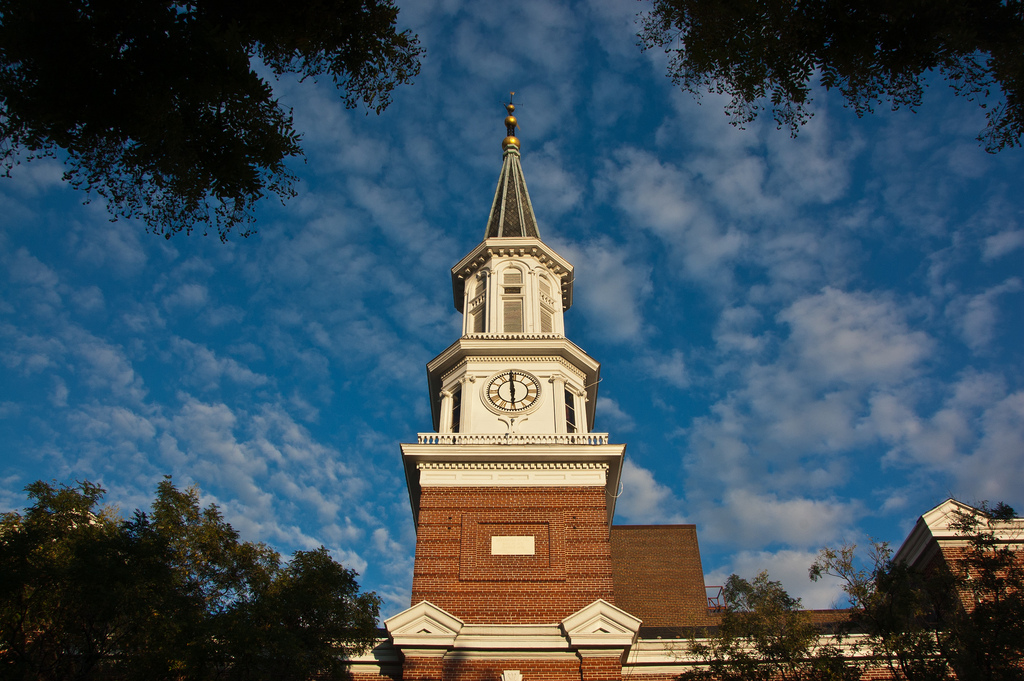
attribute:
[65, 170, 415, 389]
cloud — puffy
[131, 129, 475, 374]
sky — puffy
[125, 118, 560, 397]
cloud — puffy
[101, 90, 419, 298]
sky — puffy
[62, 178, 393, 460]
cloud — puffy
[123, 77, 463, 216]
cloud — puffy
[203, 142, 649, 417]
cloud — puffy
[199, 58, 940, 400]
sky — puffy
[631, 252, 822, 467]
cloud — puffy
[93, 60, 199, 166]
tree — leafy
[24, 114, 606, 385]
clouds — white